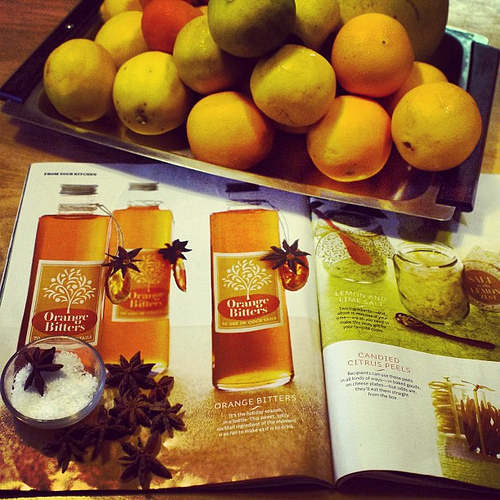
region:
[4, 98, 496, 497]
a magazine on a table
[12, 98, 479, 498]
an open magazine on a table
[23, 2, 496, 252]
a pile of oranges on a plate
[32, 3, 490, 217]
a pile of fruit on a plate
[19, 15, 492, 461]
a plate on top of a magazine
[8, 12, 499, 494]
a plate on top of an open magazine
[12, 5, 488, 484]
a magazine under a plate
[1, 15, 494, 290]
a plate of fruit on a table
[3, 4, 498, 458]
a plate of fruit on table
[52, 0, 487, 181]
a tray of fruits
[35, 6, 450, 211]
a tray of citrus fruits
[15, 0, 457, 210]
a tray of oranges, lemons, and limes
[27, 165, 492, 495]
an open magazine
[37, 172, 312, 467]
an image in a magazine depicting alcohol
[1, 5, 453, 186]
fruits on a metal tray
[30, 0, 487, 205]
pile of fruit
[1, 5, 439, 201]
a metal tray piled with fruit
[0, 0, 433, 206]
citrus fruits piled high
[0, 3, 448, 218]
a metal tray of citrus fruits on a wooden surface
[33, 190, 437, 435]
Magazine is open.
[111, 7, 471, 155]
lemon is yellow and green color.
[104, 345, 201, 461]
Star anise is brown color.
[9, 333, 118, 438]
Bowl is made of glass.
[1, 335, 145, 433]
Bowl is kept in top of magazine.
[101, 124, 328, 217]
tray is silver color.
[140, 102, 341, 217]
Lemons are in tray.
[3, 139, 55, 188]
table is brown color.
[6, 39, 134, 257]
Magazine is in the table.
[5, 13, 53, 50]
Table is made of wood.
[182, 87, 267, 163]
a round orange fruit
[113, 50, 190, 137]
a round orange fruit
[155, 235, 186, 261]
a brown star anise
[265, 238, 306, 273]
a brown star anise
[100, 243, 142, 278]
a brown star anise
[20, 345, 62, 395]
a brown star anise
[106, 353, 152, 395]
a brown star anise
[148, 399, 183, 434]
a brown star anise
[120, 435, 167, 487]
a brown star anise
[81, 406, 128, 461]
a brown star anise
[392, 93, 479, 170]
orange citrus fruit in bowl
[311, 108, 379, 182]
orange citrus fruit in bowl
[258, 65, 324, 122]
orange citrus fruit in bowl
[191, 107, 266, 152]
orange citrus fruit in bowl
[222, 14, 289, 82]
orange citrus fruit in bowl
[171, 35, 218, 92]
orange citrus fruit in bowl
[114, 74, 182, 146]
orange citrus fruit in bowl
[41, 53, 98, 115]
orange citrus fruit in bowl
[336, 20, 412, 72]
orange citrus fruit in bowl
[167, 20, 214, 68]
orange citrus fruit in bowl